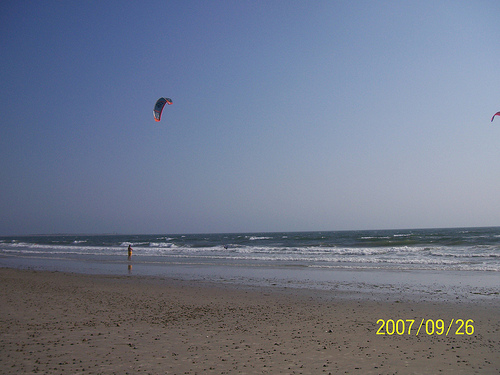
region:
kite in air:
[141, 86, 183, 121]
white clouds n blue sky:
[328, 65, 409, 136]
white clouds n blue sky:
[301, 142, 362, 189]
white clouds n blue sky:
[395, 122, 482, 180]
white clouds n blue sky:
[242, 48, 300, 98]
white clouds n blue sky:
[130, 119, 202, 197]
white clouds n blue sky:
[77, 12, 112, 59]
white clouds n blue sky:
[60, 105, 114, 160]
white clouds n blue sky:
[38, 145, 105, 187]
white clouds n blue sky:
[228, 201, 279, 225]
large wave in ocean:
[136, 239, 177, 249]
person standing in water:
[125, 242, 134, 257]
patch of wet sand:
[146, 276, 203, 293]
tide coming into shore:
[300, 261, 395, 272]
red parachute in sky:
[149, 96, 176, 124]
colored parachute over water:
[489, 109, 499, 121]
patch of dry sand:
[74, 342, 134, 367]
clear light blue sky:
[299, 21, 357, 49]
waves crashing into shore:
[341, 245, 423, 265]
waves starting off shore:
[360, 233, 386, 239]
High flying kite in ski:
[146, 92, 181, 128]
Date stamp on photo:
[363, 315, 487, 342]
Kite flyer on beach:
[119, 244, 137, 269]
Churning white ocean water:
[309, 247, 360, 259]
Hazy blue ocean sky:
[68, 187, 154, 213]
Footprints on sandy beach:
[184, 315, 241, 350]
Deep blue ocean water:
[301, 234, 340, 245]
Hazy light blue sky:
[337, 154, 413, 186]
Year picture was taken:
[360, 315, 415, 337]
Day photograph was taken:
[452, 317, 480, 345]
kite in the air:
[137, 89, 188, 127]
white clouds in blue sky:
[260, 99, 325, 159]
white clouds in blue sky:
[355, 73, 455, 148]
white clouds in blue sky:
[235, 168, 306, 239]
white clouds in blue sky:
[310, 105, 385, 186]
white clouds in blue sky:
[172, 148, 246, 190]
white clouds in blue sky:
[112, 148, 166, 203]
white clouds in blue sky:
[40, 133, 134, 200]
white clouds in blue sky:
[245, 55, 362, 122]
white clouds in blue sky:
[328, 55, 389, 133]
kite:
[148, 93, 198, 131]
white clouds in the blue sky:
[327, 53, 388, 88]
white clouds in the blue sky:
[300, 71, 348, 131]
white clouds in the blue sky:
[402, 99, 450, 150]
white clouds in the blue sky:
[288, 119, 355, 184]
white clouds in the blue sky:
[202, 182, 270, 259]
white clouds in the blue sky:
[67, 121, 109, 188]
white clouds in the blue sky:
[150, 165, 202, 195]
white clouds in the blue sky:
[64, 41, 101, 95]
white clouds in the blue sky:
[62, 148, 130, 215]